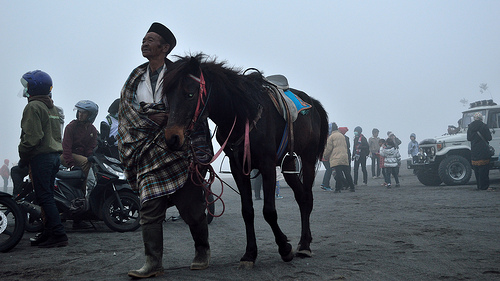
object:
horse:
[157, 50, 331, 272]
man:
[114, 22, 220, 277]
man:
[14, 66, 71, 249]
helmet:
[17, 69, 53, 96]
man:
[59, 96, 106, 170]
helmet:
[72, 99, 100, 123]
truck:
[406, 89, 500, 191]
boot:
[128, 222, 168, 278]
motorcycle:
[10, 123, 147, 235]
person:
[377, 141, 404, 189]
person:
[324, 121, 355, 196]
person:
[348, 124, 369, 187]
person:
[465, 113, 493, 192]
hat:
[473, 110, 484, 120]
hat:
[331, 120, 341, 132]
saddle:
[233, 66, 314, 125]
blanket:
[113, 57, 212, 207]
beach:
[0, 164, 500, 281]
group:
[320, 118, 500, 195]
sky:
[0, 2, 500, 143]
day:
[0, 2, 500, 278]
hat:
[147, 22, 179, 49]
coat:
[379, 147, 402, 169]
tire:
[437, 151, 475, 185]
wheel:
[100, 188, 146, 233]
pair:
[127, 211, 214, 280]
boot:
[185, 210, 213, 272]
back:
[261, 74, 314, 123]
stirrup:
[277, 150, 305, 175]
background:
[0, 0, 499, 236]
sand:
[0, 162, 499, 280]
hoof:
[273, 249, 298, 263]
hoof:
[231, 251, 258, 271]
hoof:
[297, 242, 314, 258]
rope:
[183, 135, 227, 222]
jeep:
[405, 93, 500, 199]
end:
[405, 126, 478, 185]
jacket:
[319, 130, 353, 171]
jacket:
[465, 120, 493, 166]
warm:
[108, 51, 212, 207]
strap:
[286, 125, 302, 156]